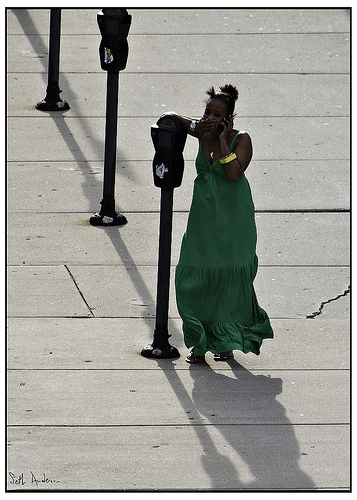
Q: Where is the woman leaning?
A: On a parking meter.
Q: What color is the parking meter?
A: Black.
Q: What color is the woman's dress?
A: Green.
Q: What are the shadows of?
A: The woman and the parking meters.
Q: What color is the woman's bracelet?
A: Yellow.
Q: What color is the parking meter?
A: Black.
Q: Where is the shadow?
A: On the ground.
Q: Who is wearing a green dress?
A: A woman.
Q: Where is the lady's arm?
A: On the parking meter.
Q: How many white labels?
A: Two.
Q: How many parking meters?
A: Three.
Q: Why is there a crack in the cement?
A: The cement shrinks.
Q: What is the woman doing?
A: Talking on the phone.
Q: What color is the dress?
A: Green.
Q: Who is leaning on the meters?
A: A woman.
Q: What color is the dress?
A: Green.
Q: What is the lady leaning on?
A: A meter.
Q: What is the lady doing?
A: Talking on the phone.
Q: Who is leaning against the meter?
A: A lady.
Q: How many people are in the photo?
A: 1.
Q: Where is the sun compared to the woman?
A: Behind her.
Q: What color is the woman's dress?
A: Green.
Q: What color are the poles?
A: Black.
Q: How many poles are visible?
A: 3.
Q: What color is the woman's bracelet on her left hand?
A: Yellow.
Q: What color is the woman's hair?
A: Black.